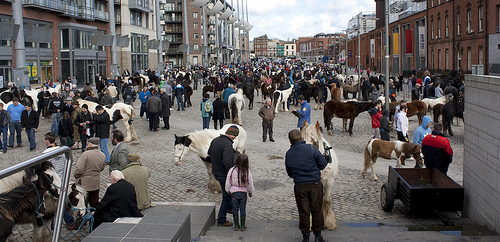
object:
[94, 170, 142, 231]
man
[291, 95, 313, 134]
person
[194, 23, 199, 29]
window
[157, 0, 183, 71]
building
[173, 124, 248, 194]
horse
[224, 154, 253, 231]
girl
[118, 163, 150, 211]
jacket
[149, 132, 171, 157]
ground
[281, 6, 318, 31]
cloud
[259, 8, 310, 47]
sky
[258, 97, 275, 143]
people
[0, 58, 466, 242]
crowd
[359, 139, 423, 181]
pony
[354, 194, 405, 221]
brick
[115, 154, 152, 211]
men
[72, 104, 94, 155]
lady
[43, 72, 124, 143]
group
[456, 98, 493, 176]
wall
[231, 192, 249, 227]
jean